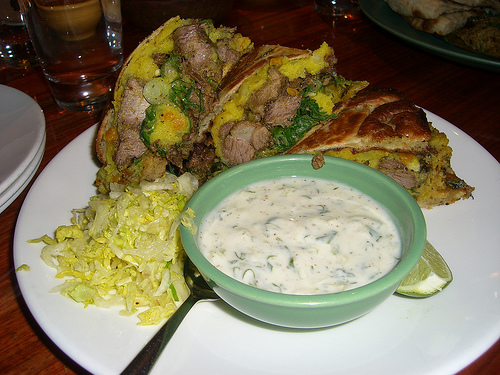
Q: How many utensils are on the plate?
A: One.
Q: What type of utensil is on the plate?
A: A spoon.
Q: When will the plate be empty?
A: When the food is gone.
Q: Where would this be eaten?
A: A restaurant.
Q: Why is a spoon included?
A: To serve the topping in the bowl.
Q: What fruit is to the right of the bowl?
A: A lime.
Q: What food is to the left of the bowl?
A: Lettuce.